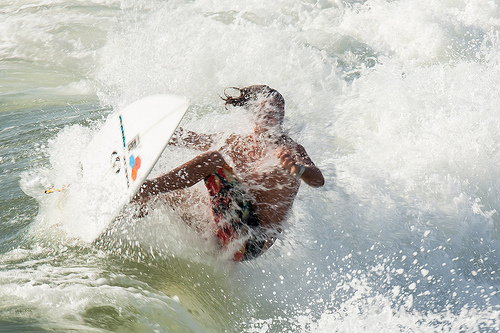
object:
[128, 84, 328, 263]
person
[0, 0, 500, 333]
ocean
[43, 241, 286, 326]
wave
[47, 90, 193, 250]
surfboard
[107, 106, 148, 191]
stickers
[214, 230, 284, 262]
butt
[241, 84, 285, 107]
hair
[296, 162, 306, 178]
wristband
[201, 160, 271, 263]
shorts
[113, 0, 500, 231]
water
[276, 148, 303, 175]
hand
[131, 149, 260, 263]
leg